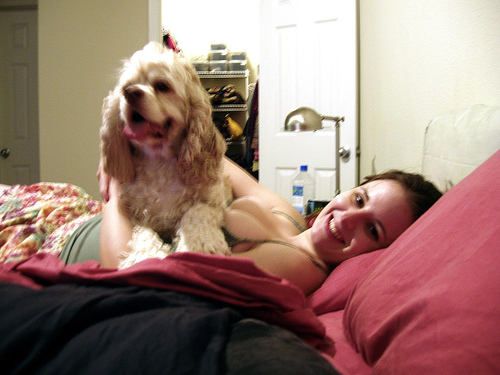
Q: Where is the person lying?
A: In bed.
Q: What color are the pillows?
A: Red.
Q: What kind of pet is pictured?
A: Dog.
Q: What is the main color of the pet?
A: White.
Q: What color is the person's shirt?
A: Grey.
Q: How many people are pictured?
A: One.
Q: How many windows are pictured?
A: None.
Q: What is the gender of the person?
A: Female.